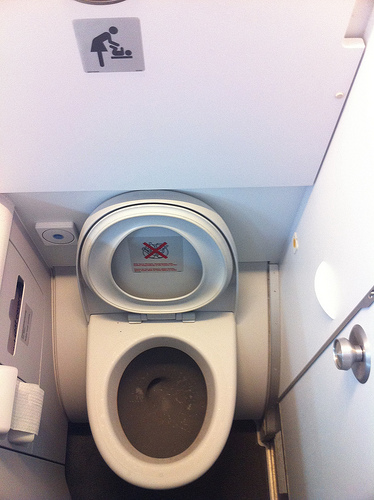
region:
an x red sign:
[119, 223, 176, 262]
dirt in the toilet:
[137, 408, 173, 445]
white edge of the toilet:
[140, 456, 181, 488]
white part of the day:
[319, 441, 331, 483]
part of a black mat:
[241, 461, 259, 489]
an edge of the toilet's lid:
[205, 230, 232, 282]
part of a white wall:
[254, 204, 276, 226]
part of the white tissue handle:
[0, 364, 7, 408]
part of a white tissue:
[18, 389, 38, 429]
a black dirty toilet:
[122, 306, 214, 457]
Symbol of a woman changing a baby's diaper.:
[68, 17, 143, 76]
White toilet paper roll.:
[12, 379, 44, 436]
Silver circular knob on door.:
[329, 320, 372, 384]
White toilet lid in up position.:
[80, 201, 234, 323]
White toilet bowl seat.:
[84, 312, 242, 492]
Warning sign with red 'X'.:
[127, 237, 184, 272]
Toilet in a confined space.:
[73, 189, 239, 490]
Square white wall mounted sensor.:
[32, 221, 80, 247]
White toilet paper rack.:
[1, 363, 45, 445]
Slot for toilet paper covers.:
[0, 237, 47, 387]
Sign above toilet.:
[61, 7, 164, 80]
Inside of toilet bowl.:
[99, 334, 260, 497]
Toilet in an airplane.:
[45, 226, 275, 476]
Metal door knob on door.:
[321, 326, 363, 393]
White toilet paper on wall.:
[8, 375, 51, 448]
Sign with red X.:
[144, 237, 195, 287]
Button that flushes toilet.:
[36, 214, 81, 269]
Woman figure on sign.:
[88, 27, 137, 67]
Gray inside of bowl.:
[129, 353, 229, 456]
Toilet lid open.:
[75, 204, 260, 318]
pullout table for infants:
[6, 7, 317, 181]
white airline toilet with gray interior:
[65, 189, 243, 487]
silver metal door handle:
[314, 318, 370, 389]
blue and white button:
[30, 220, 79, 249]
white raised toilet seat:
[76, 202, 232, 314]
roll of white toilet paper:
[2, 363, 46, 443]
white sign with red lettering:
[126, 234, 186, 274]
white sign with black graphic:
[124, 235, 189, 274]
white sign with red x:
[127, 236, 186, 274]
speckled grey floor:
[67, 428, 279, 497]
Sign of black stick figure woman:
[71, 21, 117, 72]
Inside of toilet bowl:
[138, 382, 183, 442]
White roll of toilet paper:
[20, 386, 46, 443]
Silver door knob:
[336, 324, 366, 391]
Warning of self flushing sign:
[138, 240, 180, 280]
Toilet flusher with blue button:
[35, 220, 72, 262]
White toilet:
[77, 210, 267, 493]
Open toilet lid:
[73, 206, 244, 342]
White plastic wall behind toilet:
[240, 40, 372, 187]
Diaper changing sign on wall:
[62, 11, 158, 97]